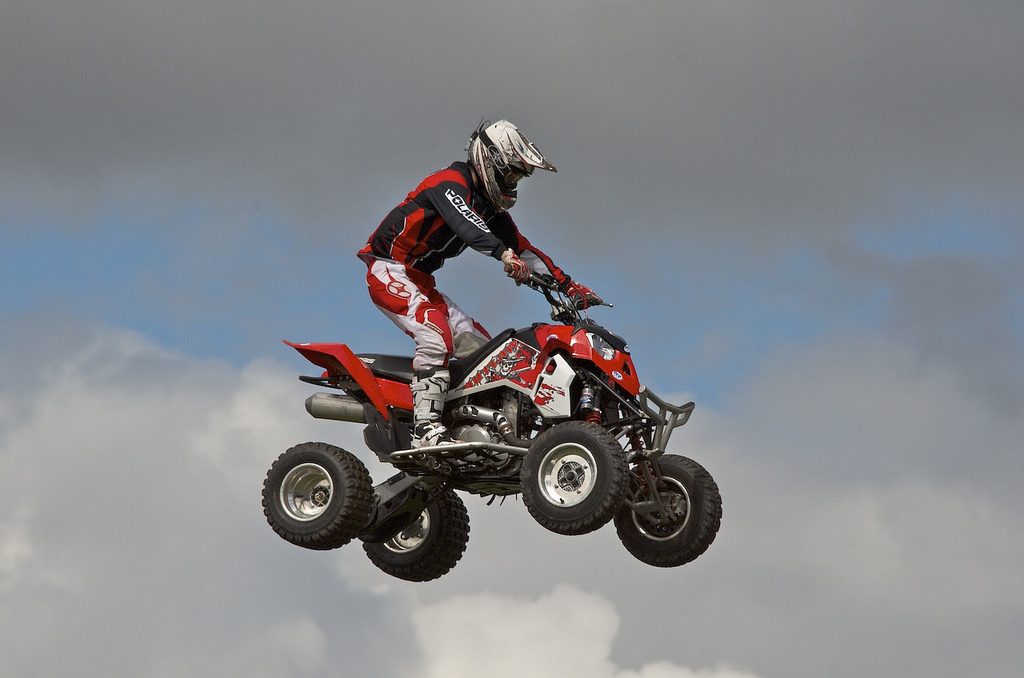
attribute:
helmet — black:
[447, 115, 619, 214]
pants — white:
[344, 273, 580, 466]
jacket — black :
[353, 182, 551, 307]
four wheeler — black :
[353, 331, 783, 486]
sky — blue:
[66, 144, 1022, 594]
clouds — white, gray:
[66, 144, 1022, 594]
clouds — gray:
[153, 254, 1020, 321]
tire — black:
[529, 426, 616, 526]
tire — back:
[258, 442, 364, 548]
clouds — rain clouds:
[73, 32, 741, 137]